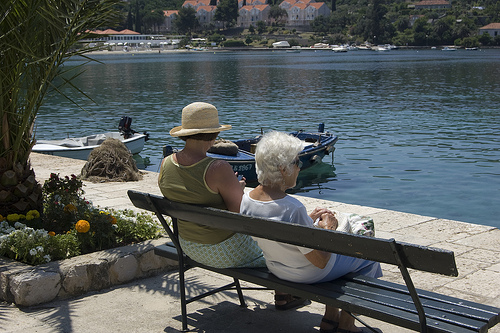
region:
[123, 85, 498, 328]
Two ladies on the bench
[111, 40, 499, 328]
two ladies by the lake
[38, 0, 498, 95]
dewy lake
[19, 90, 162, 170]
small white boat on the water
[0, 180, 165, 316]
small garden with many flowers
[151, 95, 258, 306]
lady wearing a beige hat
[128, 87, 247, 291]
lady wearing a olive green tank top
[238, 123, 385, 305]
lady with grey hair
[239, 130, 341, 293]
lady wearing a white shirt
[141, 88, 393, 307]
two ladies next to each other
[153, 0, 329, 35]
Distant tan colored buildings.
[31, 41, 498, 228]
An expanse of blue water.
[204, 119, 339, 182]
A blue colored boat.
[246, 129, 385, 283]
A lady sitting down.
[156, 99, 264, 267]
A lady wearing green.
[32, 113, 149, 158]
A white boat in the water.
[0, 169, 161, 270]
A planting of flowers.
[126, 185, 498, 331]
A dark colored bench.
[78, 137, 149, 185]
A pile of debri.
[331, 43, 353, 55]
A boat out on the water.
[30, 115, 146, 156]
a small blue boat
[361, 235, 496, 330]
a park bench on the seawall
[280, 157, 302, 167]
the lady is wearing black sunglasses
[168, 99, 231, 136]
a wide brimmed hat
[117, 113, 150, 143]
an outboard motor on the boat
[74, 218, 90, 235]
an orange flower in the flower bed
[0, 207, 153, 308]
a concrete flower bed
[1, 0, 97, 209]
a palm tree in the flower bed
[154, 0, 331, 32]
a development across the bay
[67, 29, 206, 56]
a resort and beach across the bay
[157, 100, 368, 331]
older women setting on park bench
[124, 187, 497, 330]
black wooden bench occupied by two women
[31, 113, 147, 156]
small motorboat parked against shore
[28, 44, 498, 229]
large scenic lake in front of women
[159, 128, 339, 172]
second parked motorboat is blue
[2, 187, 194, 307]
small upraised flower bed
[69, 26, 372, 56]
beach scene on other side of the lake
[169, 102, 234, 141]
woman on the left is wearing a hat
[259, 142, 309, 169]
woman on the right wearing dark sunglasses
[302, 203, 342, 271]
hands clasped in lap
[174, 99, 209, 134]
Person wearing hat on head.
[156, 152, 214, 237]
Person wearing tank top.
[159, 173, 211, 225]
Person wearing green shirt.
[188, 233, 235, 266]
Person wearing light blue printed skirt.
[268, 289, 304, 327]
Person wearing brown sandals.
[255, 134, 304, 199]
Person has gray hair.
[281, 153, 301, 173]
Glasses on woman's face.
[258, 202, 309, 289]
Woman wearing white shirt.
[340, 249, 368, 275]
Woman wearing blue pants.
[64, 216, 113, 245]
Orange flower in flower bed.